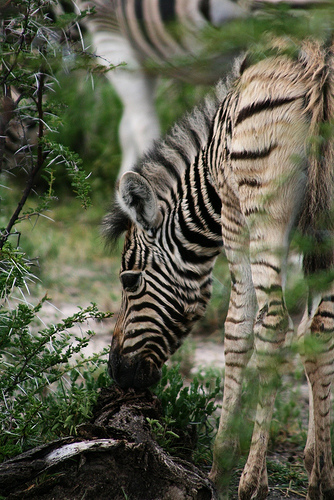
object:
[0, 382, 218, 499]
grass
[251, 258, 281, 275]
stripe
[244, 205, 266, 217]
stripe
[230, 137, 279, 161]
stripe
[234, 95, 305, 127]
stripe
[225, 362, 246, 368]
stripe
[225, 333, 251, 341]
stripe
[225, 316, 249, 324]
stripe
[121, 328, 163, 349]
stripe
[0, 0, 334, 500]
forest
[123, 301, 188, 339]
stripes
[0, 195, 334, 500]
ground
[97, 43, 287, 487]
zebra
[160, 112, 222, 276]
neck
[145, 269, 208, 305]
stripes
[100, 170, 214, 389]
head down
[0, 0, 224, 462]
plants